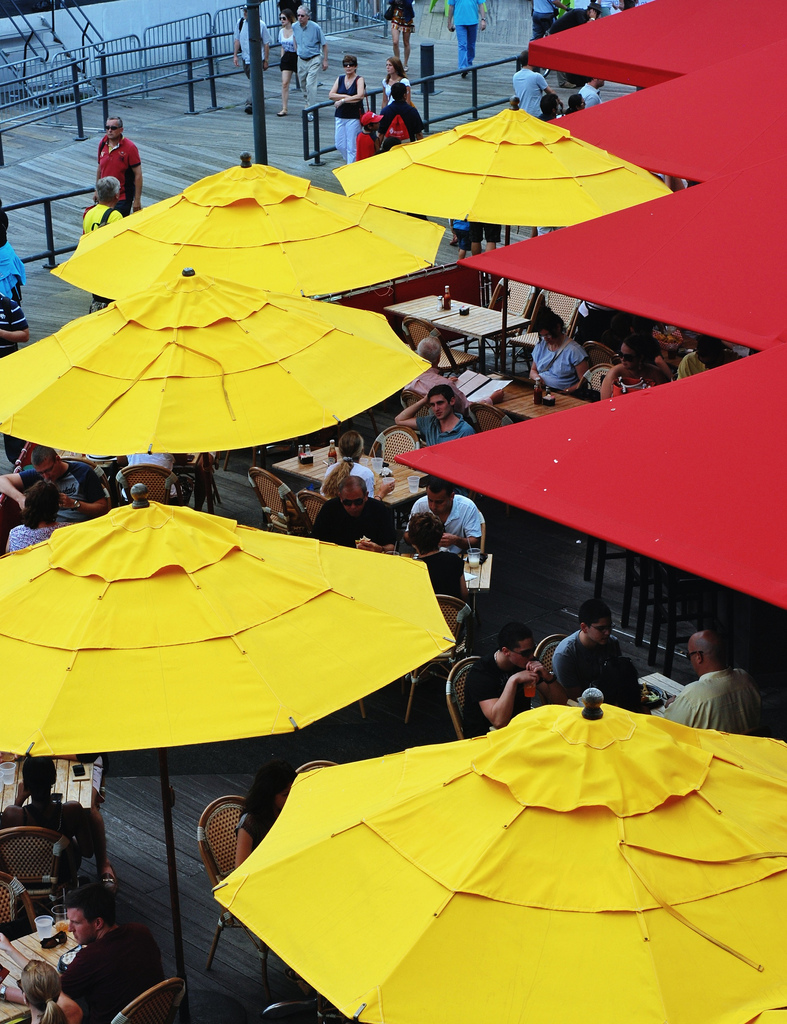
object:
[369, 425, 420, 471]
chair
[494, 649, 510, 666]
neck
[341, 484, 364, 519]
face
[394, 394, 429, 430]
arm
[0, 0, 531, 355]
pier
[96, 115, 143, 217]
man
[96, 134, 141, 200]
shirt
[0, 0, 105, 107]
steps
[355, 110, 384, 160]
man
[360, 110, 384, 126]
cap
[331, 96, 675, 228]
umbrella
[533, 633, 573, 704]
chair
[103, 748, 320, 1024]
floor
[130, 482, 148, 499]
tip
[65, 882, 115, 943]
head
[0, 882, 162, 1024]
man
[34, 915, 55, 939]
cup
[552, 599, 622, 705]
man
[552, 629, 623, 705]
shirt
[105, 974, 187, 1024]
chair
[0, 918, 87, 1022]
table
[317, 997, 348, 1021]
table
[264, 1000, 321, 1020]
chair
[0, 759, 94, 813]
table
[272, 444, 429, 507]
table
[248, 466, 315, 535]
chair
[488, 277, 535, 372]
chair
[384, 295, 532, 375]
table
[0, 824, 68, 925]
chair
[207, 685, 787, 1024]
umbrella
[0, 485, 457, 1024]
umbrella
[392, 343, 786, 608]
umbrella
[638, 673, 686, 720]
table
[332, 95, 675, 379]
umbrella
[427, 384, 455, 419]
head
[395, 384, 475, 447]
man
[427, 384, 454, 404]
hair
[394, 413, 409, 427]
elbow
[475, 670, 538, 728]
arm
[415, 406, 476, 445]
shirt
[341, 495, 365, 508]
sunglasses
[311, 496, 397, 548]
shirt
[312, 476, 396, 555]
man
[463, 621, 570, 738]
man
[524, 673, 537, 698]
cup